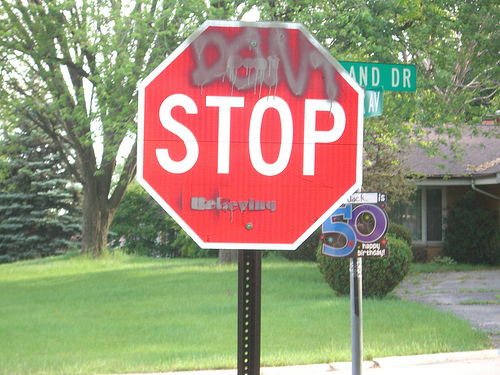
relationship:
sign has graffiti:
[134, 20, 369, 252] [182, 25, 343, 100]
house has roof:
[380, 120, 500, 264] [395, 119, 499, 175]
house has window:
[380, 120, 500, 264] [407, 185, 446, 245]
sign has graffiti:
[134, 20, 369, 252] [193, 194, 280, 219]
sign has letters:
[134, 20, 369, 252] [153, 88, 346, 178]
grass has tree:
[1, 249, 495, 374] [0, 96, 86, 267]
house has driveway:
[380, 120, 500, 264] [392, 268, 499, 352]